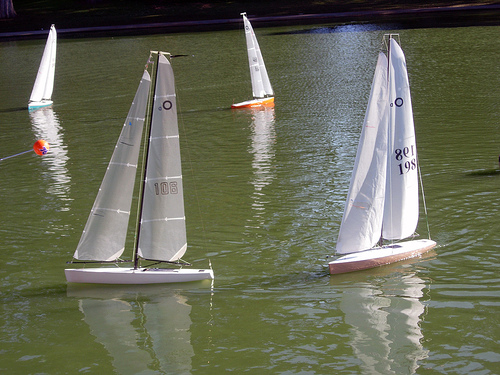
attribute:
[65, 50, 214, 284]
toy boat — white, floating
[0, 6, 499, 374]
water — green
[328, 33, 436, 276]
toy boat — mauve, pink, floating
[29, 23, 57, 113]
toy boat — light blue, green, small, blue, floating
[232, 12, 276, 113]
toy boat — orange, small, floating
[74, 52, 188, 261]
sail — white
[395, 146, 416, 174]
numbers — black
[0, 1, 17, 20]
trunk — large, brown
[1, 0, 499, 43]
ledge — concrete, gray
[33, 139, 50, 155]
fishing bobber — orange, flying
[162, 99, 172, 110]
circle — black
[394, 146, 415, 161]
numbers — backwards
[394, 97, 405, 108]
circle — black